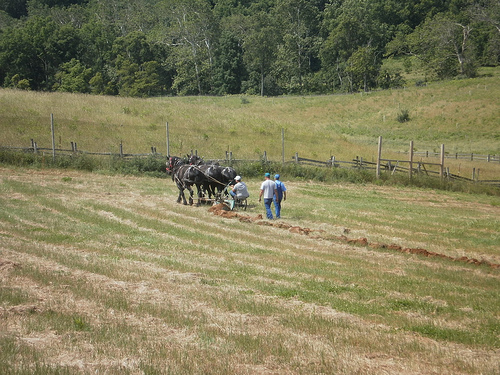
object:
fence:
[2, 115, 500, 190]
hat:
[264, 173, 270, 178]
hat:
[274, 174, 280, 179]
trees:
[0, 0, 499, 97]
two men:
[259, 172, 288, 220]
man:
[258, 173, 279, 220]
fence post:
[439, 144, 444, 176]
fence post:
[376, 134, 382, 178]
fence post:
[408, 140, 413, 181]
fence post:
[281, 128, 284, 163]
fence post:
[165, 122, 170, 158]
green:
[395, 109, 410, 123]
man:
[273, 173, 287, 219]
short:
[263, 198, 274, 220]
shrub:
[0, 84, 500, 152]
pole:
[50, 113, 55, 161]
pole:
[31, 139, 38, 154]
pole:
[70, 141, 74, 155]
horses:
[165, 149, 237, 206]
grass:
[1, 79, 500, 374]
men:
[255, 167, 288, 222]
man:
[229, 175, 250, 203]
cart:
[205, 182, 249, 214]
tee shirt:
[260, 179, 278, 198]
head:
[166, 155, 176, 175]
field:
[2, 160, 499, 375]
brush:
[0, 0, 499, 96]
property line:
[0, 140, 500, 192]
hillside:
[2, 75, 500, 178]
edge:
[2, 146, 496, 193]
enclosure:
[0, 162, 500, 374]